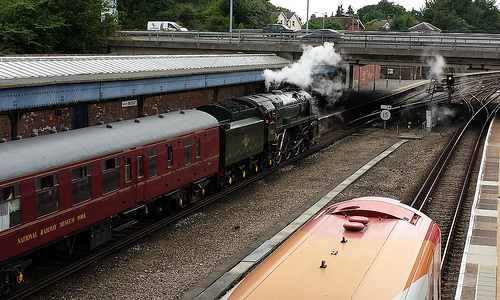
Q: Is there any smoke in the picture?
A: Yes, there is smoke.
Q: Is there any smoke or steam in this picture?
A: Yes, there is smoke.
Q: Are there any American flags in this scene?
A: No, there are no American flags.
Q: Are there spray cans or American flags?
A: No, there are no American flags or spray cans.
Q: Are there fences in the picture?
A: No, there are no fences.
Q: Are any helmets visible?
A: No, there are no helmets.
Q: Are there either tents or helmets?
A: No, there are no helmets or tents.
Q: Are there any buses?
A: No, there are no buses.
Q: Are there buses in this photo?
A: No, there are no buses.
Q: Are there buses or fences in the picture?
A: No, there are no buses or fences.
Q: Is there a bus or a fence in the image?
A: No, there are no buses or fences.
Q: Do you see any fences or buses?
A: No, there are no buses or fences.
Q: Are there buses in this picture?
A: No, there are no buses.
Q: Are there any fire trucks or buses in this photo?
A: No, there are no buses or fire trucks.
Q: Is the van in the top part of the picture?
A: Yes, the van is in the top of the image.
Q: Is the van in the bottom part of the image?
A: No, the van is in the top of the image.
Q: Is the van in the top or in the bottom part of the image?
A: The van is in the top of the image.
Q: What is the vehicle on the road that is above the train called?
A: The vehicle is a van.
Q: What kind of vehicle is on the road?
A: The vehicle is a van.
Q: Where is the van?
A: The van is on the road.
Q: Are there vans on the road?
A: Yes, there is a van on the road.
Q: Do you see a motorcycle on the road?
A: No, there is a van on the road.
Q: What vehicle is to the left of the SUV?
A: The vehicle is a van.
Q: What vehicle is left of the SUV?
A: The vehicle is a van.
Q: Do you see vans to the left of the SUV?
A: Yes, there is a van to the left of the SUV.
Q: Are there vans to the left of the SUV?
A: Yes, there is a van to the left of the SUV.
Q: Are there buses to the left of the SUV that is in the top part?
A: No, there is a van to the left of the SUV.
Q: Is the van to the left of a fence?
A: No, the van is to the left of the SUV.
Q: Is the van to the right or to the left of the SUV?
A: The van is to the left of the SUV.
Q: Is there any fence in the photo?
A: No, there are no fences.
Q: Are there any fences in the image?
A: No, there are no fences.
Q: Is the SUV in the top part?
A: Yes, the SUV is in the top of the image.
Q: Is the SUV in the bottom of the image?
A: No, the SUV is in the top of the image.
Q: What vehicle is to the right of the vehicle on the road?
A: The vehicle is a SUV.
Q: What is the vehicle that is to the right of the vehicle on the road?
A: The vehicle is a SUV.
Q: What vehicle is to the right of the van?
A: The vehicle is a SUV.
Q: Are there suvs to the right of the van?
A: Yes, there is a SUV to the right of the van.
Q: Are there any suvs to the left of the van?
A: No, the SUV is to the right of the van.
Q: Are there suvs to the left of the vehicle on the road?
A: No, the SUV is to the right of the van.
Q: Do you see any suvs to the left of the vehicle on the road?
A: No, the SUV is to the right of the van.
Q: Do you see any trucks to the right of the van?
A: No, there is a SUV to the right of the van.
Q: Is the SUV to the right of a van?
A: Yes, the SUV is to the right of a van.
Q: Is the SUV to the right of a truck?
A: No, the SUV is to the right of a van.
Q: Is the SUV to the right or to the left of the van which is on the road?
A: The SUV is to the right of the van.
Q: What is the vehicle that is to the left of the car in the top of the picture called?
A: The vehicle is a SUV.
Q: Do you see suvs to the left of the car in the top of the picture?
A: Yes, there is a SUV to the left of the car.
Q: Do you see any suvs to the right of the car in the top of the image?
A: No, the SUV is to the left of the car.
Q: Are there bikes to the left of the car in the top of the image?
A: No, there is a SUV to the left of the car.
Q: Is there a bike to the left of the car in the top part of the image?
A: No, there is a SUV to the left of the car.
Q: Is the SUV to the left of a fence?
A: No, the SUV is to the left of the car.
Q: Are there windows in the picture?
A: Yes, there is a window.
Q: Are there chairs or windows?
A: Yes, there is a window.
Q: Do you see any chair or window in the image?
A: Yes, there is a window.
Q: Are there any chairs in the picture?
A: No, there are no chairs.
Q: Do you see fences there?
A: No, there are no fences.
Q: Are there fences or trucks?
A: No, there are no fences or trucks.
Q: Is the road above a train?
A: Yes, the road is above a train.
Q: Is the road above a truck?
A: No, the road is above a train.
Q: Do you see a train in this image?
A: Yes, there is a train.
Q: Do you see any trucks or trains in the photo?
A: Yes, there is a train.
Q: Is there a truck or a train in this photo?
A: Yes, there is a train.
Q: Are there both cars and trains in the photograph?
A: Yes, there are both a train and cars.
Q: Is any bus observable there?
A: No, there are no buses.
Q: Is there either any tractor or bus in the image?
A: No, there are no buses or tractors.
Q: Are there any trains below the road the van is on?
A: Yes, there is a train below the road.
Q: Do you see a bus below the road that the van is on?
A: No, there is a train below the road.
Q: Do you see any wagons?
A: No, there are no wagons.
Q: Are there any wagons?
A: No, there are no wagons.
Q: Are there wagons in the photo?
A: No, there are no wagons.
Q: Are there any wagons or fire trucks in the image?
A: No, there are no wagons or fire trucks.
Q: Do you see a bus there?
A: No, there are no buses.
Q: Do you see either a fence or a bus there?
A: No, there are no buses or fences.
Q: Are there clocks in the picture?
A: No, there are no clocks.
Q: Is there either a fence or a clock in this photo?
A: No, there are no clocks or fences.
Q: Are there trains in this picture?
A: Yes, there is a train.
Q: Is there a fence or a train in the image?
A: Yes, there is a train.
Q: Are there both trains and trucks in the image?
A: No, there is a train but no trucks.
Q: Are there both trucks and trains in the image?
A: No, there is a train but no trucks.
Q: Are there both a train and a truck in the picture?
A: No, there is a train but no trucks.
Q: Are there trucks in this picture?
A: No, there are no trucks.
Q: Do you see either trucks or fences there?
A: No, there are no trucks or fences.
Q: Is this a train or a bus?
A: This is a train.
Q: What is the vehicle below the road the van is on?
A: The vehicle is a train.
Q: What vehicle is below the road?
A: The vehicle is a train.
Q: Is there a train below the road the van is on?
A: Yes, there is a train below the road.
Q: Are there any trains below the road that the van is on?
A: Yes, there is a train below the road.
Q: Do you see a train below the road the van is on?
A: Yes, there is a train below the road.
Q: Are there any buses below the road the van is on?
A: No, there is a train below the road.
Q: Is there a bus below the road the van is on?
A: No, there is a train below the road.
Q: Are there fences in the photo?
A: No, there are no fences.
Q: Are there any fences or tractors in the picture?
A: No, there are no fences or tractors.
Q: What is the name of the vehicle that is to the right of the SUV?
A: The vehicle is a car.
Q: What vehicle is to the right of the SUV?
A: The vehicle is a car.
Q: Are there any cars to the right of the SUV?
A: Yes, there is a car to the right of the SUV.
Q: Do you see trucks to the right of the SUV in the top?
A: No, there is a car to the right of the SUV.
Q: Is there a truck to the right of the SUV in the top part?
A: No, there is a car to the right of the SUV.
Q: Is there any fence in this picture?
A: No, there are no fences.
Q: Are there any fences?
A: No, there are no fences.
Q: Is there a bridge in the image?
A: Yes, there is a bridge.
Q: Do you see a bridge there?
A: Yes, there is a bridge.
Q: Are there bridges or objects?
A: Yes, there is a bridge.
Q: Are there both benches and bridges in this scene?
A: No, there is a bridge but no benches.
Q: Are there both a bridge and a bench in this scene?
A: No, there is a bridge but no benches.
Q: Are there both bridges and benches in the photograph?
A: No, there is a bridge but no benches.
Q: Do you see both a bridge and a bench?
A: No, there is a bridge but no benches.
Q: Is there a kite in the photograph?
A: No, there are no kites.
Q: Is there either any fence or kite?
A: No, there are no kites or fences.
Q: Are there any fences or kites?
A: No, there are no kites or fences.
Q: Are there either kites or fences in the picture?
A: No, there are no kites or fences.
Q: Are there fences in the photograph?
A: No, there are no fences.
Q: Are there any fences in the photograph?
A: No, there are no fences.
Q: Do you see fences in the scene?
A: No, there are no fences.